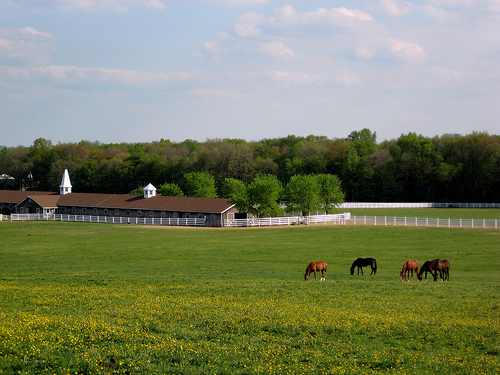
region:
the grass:
[65, 214, 188, 363]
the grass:
[101, 282, 221, 374]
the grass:
[189, 317, 242, 367]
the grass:
[134, 273, 194, 357]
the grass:
[123, 314, 189, 372]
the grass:
[101, 316, 168, 368]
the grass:
[150, 305, 216, 367]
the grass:
[151, 352, 170, 369]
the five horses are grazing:
[298, 252, 467, 291]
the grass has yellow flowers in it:
[205, 302, 294, 334]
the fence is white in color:
[372, 208, 469, 235]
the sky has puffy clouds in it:
[186, 22, 307, 78]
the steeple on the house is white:
[56, 163, 85, 203]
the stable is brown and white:
[163, 192, 228, 231]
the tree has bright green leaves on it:
[285, 177, 314, 202]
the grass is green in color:
[221, 245, 264, 268]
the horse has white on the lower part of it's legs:
[295, 257, 339, 294]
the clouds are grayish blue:
[429, 102, 481, 122]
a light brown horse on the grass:
[295, 257, 333, 287]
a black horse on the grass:
[346, 253, 383, 282]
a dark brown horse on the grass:
[416, 254, 455, 285]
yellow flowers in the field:
[1, 283, 491, 373]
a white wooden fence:
[0, 210, 499, 236]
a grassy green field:
[0, 215, 496, 291]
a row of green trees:
[135, 166, 350, 227]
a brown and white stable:
[0, 165, 263, 232]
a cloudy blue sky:
[1, 0, 498, 137]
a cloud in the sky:
[0, 21, 69, 46]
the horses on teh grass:
[303, 252, 450, 279]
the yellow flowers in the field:
[24, 284, 307, 374]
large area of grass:
[5, 220, 295, 370]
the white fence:
[327, 211, 497, 236]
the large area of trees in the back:
[47, 135, 497, 186]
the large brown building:
[1, 182, 247, 226]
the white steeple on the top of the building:
[60, 169, 73, 195]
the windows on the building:
[65, 206, 215, 225]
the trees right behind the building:
[135, 173, 341, 215]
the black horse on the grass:
[349, 257, 379, 276]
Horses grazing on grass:
[268, 251, 458, 288]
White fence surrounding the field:
[26, 204, 484, 238]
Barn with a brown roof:
[27, 176, 262, 235]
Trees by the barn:
[158, 158, 360, 231]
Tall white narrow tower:
[60, 166, 77, 197]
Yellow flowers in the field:
[49, 258, 434, 364]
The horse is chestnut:
[291, 257, 336, 284]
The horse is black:
[333, 243, 388, 278]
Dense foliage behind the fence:
[18, 121, 488, 206]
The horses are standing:
[276, 236, 469, 301]